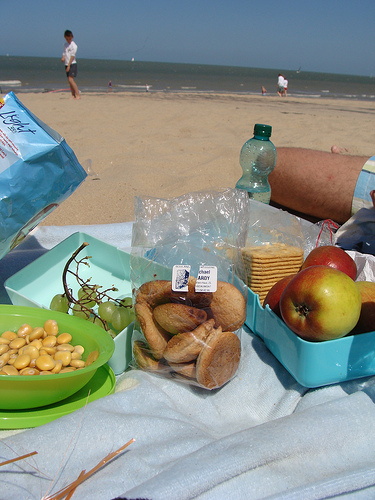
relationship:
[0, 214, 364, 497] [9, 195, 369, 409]
blanket covered with assorted foods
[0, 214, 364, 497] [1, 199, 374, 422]
blanket covered with assorted foods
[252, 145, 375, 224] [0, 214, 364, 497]
arm of a person sitting on blanket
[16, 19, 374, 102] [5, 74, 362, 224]
ocean next to beach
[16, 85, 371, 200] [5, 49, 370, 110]
beach next to ocean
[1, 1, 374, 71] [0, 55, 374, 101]
blue sky above ocean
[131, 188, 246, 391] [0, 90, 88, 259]
bag with bag of potato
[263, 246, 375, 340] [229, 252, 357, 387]
colored apple in box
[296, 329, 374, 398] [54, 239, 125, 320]
some green on vine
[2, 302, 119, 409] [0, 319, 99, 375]
bowl full of beans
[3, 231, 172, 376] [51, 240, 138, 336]
container full of grapes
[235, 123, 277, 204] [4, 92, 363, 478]
bottle on ground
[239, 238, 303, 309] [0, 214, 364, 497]
crackers on blanket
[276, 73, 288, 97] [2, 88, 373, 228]
people on beach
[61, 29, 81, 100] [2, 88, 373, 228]
body of a person on beach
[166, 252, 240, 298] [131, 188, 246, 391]
ripped label on bag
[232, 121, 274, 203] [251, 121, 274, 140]
bottle with lid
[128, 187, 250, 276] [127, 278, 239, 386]
bread in a bag full of cookies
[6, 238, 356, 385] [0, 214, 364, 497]
food on blanket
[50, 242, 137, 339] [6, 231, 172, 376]
grapes in container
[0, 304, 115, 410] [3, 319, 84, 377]
bowl of beans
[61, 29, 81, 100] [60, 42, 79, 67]
body of a person in shirt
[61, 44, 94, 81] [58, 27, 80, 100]
arm of a person of person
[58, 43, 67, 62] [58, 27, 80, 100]
arm of person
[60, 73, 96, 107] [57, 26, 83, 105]
leg of a person of person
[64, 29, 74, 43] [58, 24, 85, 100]
hair of a person of person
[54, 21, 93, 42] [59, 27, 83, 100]
hair of a person of person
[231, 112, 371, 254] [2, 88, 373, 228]
sand on a beach on beach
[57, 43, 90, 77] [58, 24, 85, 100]
body of a person of person